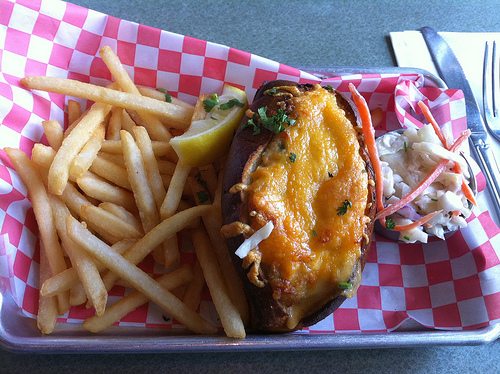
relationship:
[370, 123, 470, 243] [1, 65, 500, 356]
food on basket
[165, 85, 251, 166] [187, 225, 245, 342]
lemon on top of fry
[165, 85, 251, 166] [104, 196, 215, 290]
lemon on top of fry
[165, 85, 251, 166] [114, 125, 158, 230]
lemon on top of fry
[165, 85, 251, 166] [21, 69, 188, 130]
lemon on top of fry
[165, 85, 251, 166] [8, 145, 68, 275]
lemon on top of fry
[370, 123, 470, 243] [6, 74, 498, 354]
food on tray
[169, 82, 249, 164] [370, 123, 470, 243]
lemon on top of food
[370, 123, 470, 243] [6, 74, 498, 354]
food on top of tray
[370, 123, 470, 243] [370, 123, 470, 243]
food on top of food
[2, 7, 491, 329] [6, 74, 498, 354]
paper on top of tray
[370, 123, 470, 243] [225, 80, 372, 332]
food on top of potato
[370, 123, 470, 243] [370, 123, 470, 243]
food has food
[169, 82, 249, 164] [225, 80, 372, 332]
lemon next to potato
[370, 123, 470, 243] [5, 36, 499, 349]
food on plate